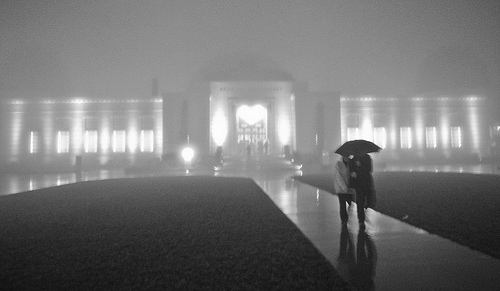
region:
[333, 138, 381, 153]
Black umbrella above people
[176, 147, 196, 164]
Bright white light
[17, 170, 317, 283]
Neatly cut grass beside sidewalk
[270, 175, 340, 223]
Gray wet sidewalk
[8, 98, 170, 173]
White pillars on front of building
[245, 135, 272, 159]
people standing in front of building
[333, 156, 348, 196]
White coat on person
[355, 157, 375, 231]
Dark clothing on person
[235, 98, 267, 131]
Bright lights in building entryway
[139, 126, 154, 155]
Window on building behind pillars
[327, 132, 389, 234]
man and woman walking under umbrella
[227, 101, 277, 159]
entrance to building with people on the stairs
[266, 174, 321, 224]
wet pavement glistening in street lights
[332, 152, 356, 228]
woman with white coat under umbrella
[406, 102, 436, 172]
lights shining on the building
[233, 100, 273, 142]
heart shaped window above door to building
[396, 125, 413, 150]
window in the front of building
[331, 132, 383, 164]
black umbrella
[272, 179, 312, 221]
reflection of light on wet sidewalk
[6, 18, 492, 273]
Two people walking, away from a building, in the rain.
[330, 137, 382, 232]
Both people are wearing jackets.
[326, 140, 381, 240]
The two people are sharing a single umbrella.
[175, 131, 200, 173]
A light.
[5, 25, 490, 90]
The building's three domes are barely visible.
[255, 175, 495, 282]
A wet sidewalk.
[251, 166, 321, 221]
Light is reflecting off the sidewalk.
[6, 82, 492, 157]
The building is being lit up by lights.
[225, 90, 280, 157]
The entrance.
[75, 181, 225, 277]
Grass.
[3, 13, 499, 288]
Gloomy scene, obscured by rain.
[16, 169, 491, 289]
Rain-covered walkway, with grass on either side.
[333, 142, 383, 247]
Couple huddled under umbrella.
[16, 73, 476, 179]
Wide, building facade.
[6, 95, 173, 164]
Lights and tall, rectangular windows on building.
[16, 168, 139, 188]
Reflection of lights on walkway.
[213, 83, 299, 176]
Large, lit entryway of building with pedestrians.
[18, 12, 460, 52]
Dark, grey gloomy sky.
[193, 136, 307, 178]
Matching planters and lights on either side of entryway.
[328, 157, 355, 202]
White coat on person, beneath dark umbrella.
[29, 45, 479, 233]
black and white picture.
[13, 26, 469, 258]
picture is taken in night time.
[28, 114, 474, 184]
lights are on.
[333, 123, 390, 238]
two people are walking in the road.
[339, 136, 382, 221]
two people are holding one umbrella.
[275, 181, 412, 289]
roads are wet.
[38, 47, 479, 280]
rainy night.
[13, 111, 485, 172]
windows are attached to the building wall.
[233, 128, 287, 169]
people are standing at the door step.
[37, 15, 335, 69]
sky is black in color.